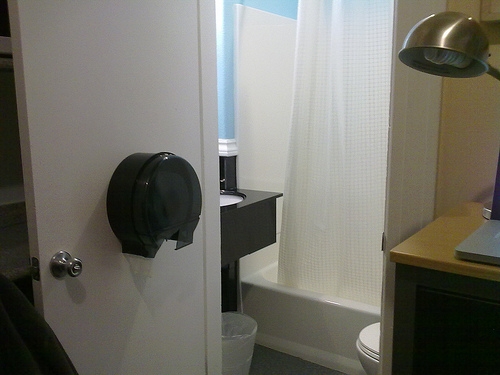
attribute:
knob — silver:
[49, 250, 85, 280]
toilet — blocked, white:
[354, 320, 379, 374]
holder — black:
[100, 151, 203, 258]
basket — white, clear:
[220, 312, 257, 374]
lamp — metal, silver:
[397, 12, 500, 85]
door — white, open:
[6, 1, 221, 374]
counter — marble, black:
[221, 188, 283, 267]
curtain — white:
[277, 2, 394, 308]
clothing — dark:
[1, 274, 77, 370]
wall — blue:
[215, 1, 235, 141]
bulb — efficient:
[423, 46, 473, 71]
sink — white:
[220, 193, 243, 207]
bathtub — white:
[239, 263, 381, 375]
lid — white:
[360, 321, 380, 353]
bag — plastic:
[221, 310, 257, 362]